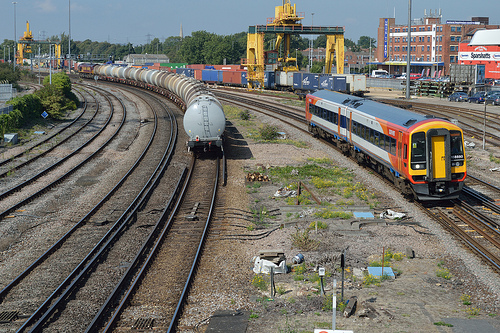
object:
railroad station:
[9, 5, 498, 332]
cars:
[469, 90, 489, 103]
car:
[447, 91, 469, 102]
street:
[401, 88, 497, 113]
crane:
[243, 0, 347, 75]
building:
[456, 27, 500, 85]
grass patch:
[255, 160, 367, 204]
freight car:
[317, 73, 333, 89]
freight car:
[221, 69, 242, 84]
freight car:
[202, 65, 224, 83]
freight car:
[329, 73, 365, 91]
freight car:
[272, 70, 293, 87]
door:
[432, 137, 446, 179]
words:
[470, 52, 491, 60]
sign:
[458, 45, 500, 65]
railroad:
[264, 83, 500, 297]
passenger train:
[303, 86, 467, 203]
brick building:
[377, 15, 487, 67]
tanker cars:
[65, 62, 227, 147]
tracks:
[0, 77, 127, 216]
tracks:
[424, 95, 500, 149]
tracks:
[0, 163, 227, 333]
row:
[306, 101, 397, 155]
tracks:
[411, 196, 500, 272]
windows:
[427, 36, 430, 42]